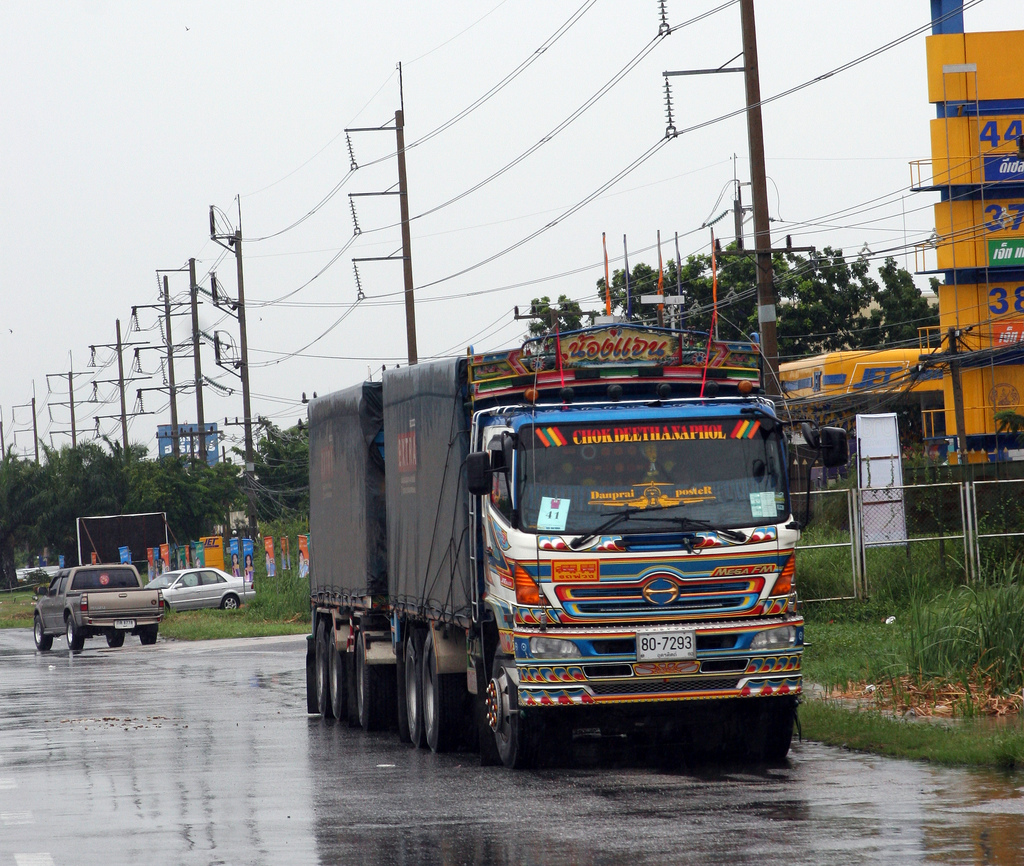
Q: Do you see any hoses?
A: No, there are no hoses.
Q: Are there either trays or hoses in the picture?
A: No, there are no hoses or trays.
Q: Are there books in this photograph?
A: No, there are no books.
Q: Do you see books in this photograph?
A: No, there are no books.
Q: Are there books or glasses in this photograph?
A: No, there are no books or glasses.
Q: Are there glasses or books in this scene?
A: No, there are no books or glasses.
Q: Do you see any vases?
A: No, there are no vases.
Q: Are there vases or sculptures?
A: No, there are no vases or sculptures.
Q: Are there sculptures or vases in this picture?
A: No, there are no vases or sculptures.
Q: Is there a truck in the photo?
A: Yes, there is a truck.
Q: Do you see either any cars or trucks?
A: Yes, there is a truck.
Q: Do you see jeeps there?
A: No, there are no jeeps.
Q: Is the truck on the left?
A: Yes, the truck is on the left of the image.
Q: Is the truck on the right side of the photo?
A: No, the truck is on the left of the image.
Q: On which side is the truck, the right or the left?
A: The truck is on the left of the image.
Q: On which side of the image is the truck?
A: The truck is on the left of the image.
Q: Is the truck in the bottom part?
A: Yes, the truck is in the bottom of the image.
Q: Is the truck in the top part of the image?
A: No, the truck is in the bottom of the image.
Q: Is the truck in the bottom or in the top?
A: The truck is in the bottom of the image.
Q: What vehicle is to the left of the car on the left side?
A: The vehicle is a truck.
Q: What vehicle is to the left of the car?
A: The vehicle is a truck.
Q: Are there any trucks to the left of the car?
A: Yes, there is a truck to the left of the car.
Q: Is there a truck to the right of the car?
A: No, the truck is to the left of the car.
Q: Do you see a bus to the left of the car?
A: No, there is a truck to the left of the car.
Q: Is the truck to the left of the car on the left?
A: Yes, the truck is to the left of the car.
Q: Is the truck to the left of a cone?
A: No, the truck is to the left of the car.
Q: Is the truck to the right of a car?
A: No, the truck is to the left of a car.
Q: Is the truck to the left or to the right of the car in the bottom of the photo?
A: The truck is to the left of the car.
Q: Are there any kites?
A: No, there are no kites.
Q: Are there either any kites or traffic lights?
A: No, there are no kites or traffic lights.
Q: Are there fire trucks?
A: No, there are no fire trucks.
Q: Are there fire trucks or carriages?
A: No, there are no fire trucks or carriages.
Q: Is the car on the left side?
A: Yes, the car is on the left of the image.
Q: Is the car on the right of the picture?
A: No, the car is on the left of the image.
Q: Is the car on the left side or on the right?
A: The car is on the left of the image.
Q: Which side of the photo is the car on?
A: The car is on the left of the image.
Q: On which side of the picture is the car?
A: The car is on the left of the image.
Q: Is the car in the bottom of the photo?
A: Yes, the car is in the bottom of the image.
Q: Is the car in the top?
A: No, the car is in the bottom of the image.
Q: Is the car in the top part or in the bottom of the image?
A: The car is in the bottom of the image.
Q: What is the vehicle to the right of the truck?
A: The vehicle is a car.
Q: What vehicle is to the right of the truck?
A: The vehicle is a car.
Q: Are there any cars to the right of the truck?
A: Yes, there is a car to the right of the truck.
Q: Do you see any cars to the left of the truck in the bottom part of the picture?
A: No, the car is to the right of the truck.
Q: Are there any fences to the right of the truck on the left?
A: No, there is a car to the right of the truck.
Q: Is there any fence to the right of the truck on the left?
A: No, there is a car to the right of the truck.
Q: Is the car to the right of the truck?
A: Yes, the car is to the right of the truck.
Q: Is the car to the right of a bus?
A: No, the car is to the right of the truck.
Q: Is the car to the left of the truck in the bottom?
A: No, the car is to the right of the truck.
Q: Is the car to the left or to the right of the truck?
A: The car is to the right of the truck.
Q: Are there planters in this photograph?
A: No, there are no planters.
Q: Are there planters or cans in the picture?
A: No, there are no planters or cans.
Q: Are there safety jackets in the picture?
A: No, there are no safety jackets.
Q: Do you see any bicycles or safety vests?
A: No, there are no safety vests or bicycles.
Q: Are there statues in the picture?
A: No, there are no statues.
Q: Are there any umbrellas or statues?
A: No, there are no statues or umbrellas.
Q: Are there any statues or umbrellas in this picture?
A: No, there are no statues or umbrellas.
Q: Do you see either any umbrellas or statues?
A: No, there are no statues or umbrellas.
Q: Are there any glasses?
A: No, there are no glasses.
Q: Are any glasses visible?
A: No, there are no glasses.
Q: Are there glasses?
A: No, there are no glasses.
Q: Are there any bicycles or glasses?
A: No, there are no glasses or bicycles.